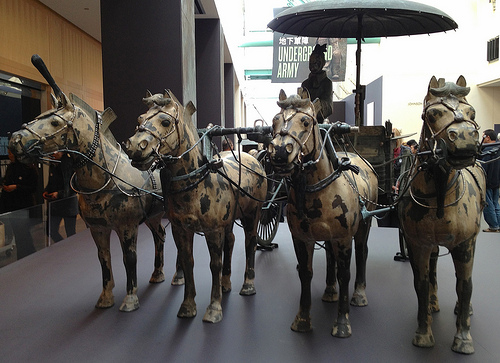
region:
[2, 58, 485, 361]
Four horse statues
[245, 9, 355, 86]
A sign saying Underground Army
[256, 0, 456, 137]
An umbrella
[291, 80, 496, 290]
people behind the statue display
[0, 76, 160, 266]
people to the right of the statue display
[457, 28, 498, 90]
a vent on the wall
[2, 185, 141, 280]
a clear shield for the statue display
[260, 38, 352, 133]
a statue of a person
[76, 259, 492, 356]
16 hooves on the display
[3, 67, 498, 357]
statue of horses and a man in a carriage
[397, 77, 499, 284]
Wooden horse in a display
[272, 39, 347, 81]
sign that says "Underground Army"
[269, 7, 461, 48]
umbrella over a horse carriage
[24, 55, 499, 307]
four wooden horses in a display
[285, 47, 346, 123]
figure of man in a horse carriage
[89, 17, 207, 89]
pillar in room of a museum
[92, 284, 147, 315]
front hooves of a wooden horse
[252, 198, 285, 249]
portion of a wheel of a horse carriage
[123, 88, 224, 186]
headshot and halter of a wooden horse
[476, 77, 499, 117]
entrance into room of a museum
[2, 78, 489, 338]
horse statues on table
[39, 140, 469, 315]
four horse statues in a row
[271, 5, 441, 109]
a dark colored umbrella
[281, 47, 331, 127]
a statue of a chariot driver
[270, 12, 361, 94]
a large hanging banner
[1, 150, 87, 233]
two pedestrians walking down a hallway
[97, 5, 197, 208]
a large roof support column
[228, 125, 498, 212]
a crowd of people in the background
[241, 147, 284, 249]
a chariot's right wheel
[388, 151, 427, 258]
a chariot's left wheel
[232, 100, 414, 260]
a chariot hitched to four horse statues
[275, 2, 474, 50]
Umbrella in the background.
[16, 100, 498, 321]
There are four horses.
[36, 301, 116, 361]
The ground is grey.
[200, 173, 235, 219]
Black on the horses.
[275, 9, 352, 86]
Sign in the background.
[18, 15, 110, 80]
The building is brown.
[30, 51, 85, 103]
Black above the horses head.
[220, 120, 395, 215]
Wagon in the background.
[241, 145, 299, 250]
The wheel is black.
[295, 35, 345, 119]
Person in the wagon.